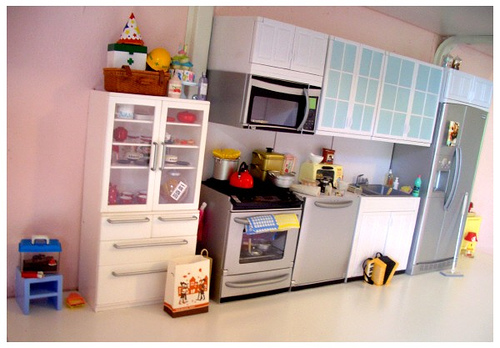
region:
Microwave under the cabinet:
[209, 62, 324, 132]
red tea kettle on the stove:
[227, 154, 253, 189]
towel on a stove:
[241, 208, 308, 239]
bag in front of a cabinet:
[140, 235, 226, 324]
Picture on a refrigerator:
[443, 120, 460, 148]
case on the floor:
[361, 247, 392, 292]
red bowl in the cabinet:
[168, 110, 198, 124]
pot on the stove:
[206, 145, 234, 185]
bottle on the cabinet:
[201, 67, 211, 102]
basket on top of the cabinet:
[99, 65, 176, 88]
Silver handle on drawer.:
[103, 209, 153, 234]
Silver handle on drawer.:
[156, 213, 206, 228]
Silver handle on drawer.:
[114, 233, 192, 253]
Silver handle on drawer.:
[118, 264, 184, 291]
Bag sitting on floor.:
[164, 252, 236, 339]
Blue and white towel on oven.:
[254, 215, 275, 246]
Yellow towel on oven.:
[275, 213, 310, 228]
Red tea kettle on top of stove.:
[227, 163, 272, 191]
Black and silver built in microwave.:
[237, 82, 329, 132]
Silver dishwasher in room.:
[313, 197, 350, 286]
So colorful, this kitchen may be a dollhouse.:
[12, 8, 495, 320]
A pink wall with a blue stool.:
[14, 152, 71, 319]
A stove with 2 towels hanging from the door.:
[206, 179, 300, 309]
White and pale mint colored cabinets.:
[327, 36, 437, 153]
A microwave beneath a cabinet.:
[212, 16, 331, 140]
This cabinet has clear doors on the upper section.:
[72, 89, 211, 313]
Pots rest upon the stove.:
[197, 139, 310, 304]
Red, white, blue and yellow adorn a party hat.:
[106, 7, 148, 53]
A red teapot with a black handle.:
[229, 159, 256, 194]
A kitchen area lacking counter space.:
[209, 131, 434, 306]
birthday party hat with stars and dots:
[106, 9, 152, 46]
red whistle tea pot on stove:
[228, 161, 260, 188]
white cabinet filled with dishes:
[94, 92, 208, 254]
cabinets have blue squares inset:
[318, 43, 445, 147]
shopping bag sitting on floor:
[163, 249, 222, 329]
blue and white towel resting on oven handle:
[238, 213, 277, 235]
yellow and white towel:
[278, 211, 304, 235]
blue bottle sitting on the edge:
[408, 175, 425, 200]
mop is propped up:
[439, 192, 474, 291]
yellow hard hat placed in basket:
[144, 43, 178, 93]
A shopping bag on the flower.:
[158, 263, 226, 318]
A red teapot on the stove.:
[230, 163, 254, 185]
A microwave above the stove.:
[227, 78, 314, 138]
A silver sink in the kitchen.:
[363, 180, 401, 198]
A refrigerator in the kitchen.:
[442, 102, 479, 268]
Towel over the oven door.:
[240, 210, 310, 230]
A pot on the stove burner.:
[266, 168, 293, 189]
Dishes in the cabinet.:
[124, 119, 187, 200]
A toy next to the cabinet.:
[11, 223, 82, 320]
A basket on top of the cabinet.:
[103, 58, 173, 92]